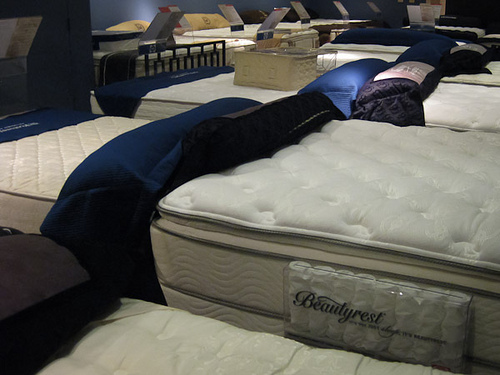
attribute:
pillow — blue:
[40, 97, 265, 306]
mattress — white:
[0, 105, 157, 238]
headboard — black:
[144, 40, 227, 78]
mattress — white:
[90, 66, 356, 118]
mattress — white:
[150, 117, 499, 373]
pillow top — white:
[157, 118, 500, 284]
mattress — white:
[321, 42, 462, 54]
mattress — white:
[175, 34, 257, 64]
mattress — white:
[184, 24, 320, 48]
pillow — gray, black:
[169, 90, 349, 189]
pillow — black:
[438, 42, 495, 81]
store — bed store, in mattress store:
[0, 17, 499, 375]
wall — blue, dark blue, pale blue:
[90, 1, 499, 37]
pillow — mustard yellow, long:
[178, 14, 230, 31]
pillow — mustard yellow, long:
[106, 18, 151, 39]